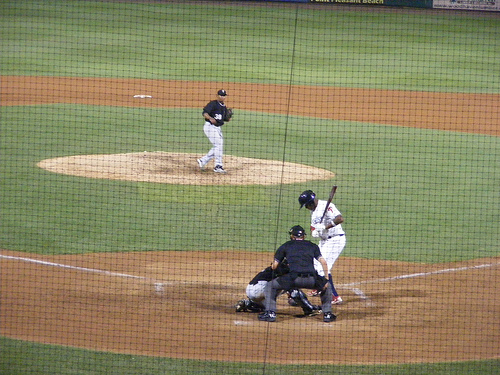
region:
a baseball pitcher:
[196, 86, 235, 173]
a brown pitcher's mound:
[40, 149, 328, 187]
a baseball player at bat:
[296, 178, 348, 285]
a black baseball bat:
[318, 184, 338, 224]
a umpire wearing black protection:
[258, 226, 338, 321]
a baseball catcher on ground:
[245, 260, 314, 311]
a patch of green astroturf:
[3, 0, 498, 93]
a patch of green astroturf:
[0, 103, 498, 266]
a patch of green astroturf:
[3, 341, 494, 373]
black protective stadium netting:
[3, 4, 498, 368]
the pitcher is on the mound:
[183, 64, 248, 180]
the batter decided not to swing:
[296, 177, 367, 302]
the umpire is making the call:
[263, 190, 354, 344]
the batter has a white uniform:
[283, 173, 378, 368]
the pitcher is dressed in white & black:
[183, 60, 248, 202]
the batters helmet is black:
[298, 174, 325, 226]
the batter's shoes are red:
[312, 282, 351, 324]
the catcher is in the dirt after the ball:
[236, 250, 307, 330]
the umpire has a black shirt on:
[264, 205, 379, 337]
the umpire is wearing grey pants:
[260, 250, 345, 340]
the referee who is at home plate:
[257, 222, 342, 326]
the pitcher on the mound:
[195, 87, 233, 170]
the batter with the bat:
[289, 180, 350, 320]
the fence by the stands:
[1, 8, 474, 372]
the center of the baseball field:
[12, 105, 475, 267]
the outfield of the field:
[4, 2, 497, 97]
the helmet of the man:
[290, 189, 314, 205]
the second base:
[126, 90, 161, 105]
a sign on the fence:
[421, 2, 498, 24]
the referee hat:
[281, 224, 308, 236]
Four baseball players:
[183, 84, 367, 325]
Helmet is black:
[291, 191, 318, 207]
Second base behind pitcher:
[135, 89, 157, 106]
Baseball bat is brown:
[318, 184, 335, 223]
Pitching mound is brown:
[48, 137, 328, 187]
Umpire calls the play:
[277, 222, 334, 319]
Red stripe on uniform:
[307, 220, 317, 235]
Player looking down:
[297, 190, 347, 235]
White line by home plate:
[10, 254, 150, 284]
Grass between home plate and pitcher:
[40, 175, 486, 252]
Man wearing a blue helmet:
[287, 176, 360, 278]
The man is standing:
[294, 186, 382, 329]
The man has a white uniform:
[296, 177, 362, 317]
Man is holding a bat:
[297, 175, 361, 312]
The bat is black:
[312, 171, 360, 271]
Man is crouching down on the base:
[246, 221, 354, 325]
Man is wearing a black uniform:
[254, 207, 377, 335]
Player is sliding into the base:
[230, 248, 301, 330]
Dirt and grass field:
[58, 43, 490, 367]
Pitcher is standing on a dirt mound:
[175, 76, 249, 197]